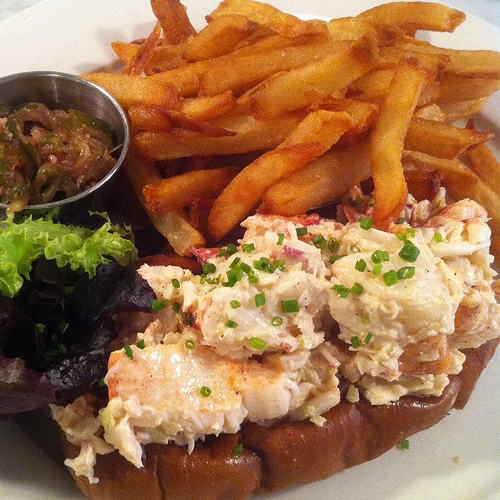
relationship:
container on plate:
[0, 68, 134, 224] [385, 467, 456, 490]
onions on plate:
[47, 218, 498, 477] [7, 0, 498, 495]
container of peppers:
[0, 59, 140, 249] [0, 87, 117, 201]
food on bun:
[7, 187, 494, 500] [122, 417, 381, 500]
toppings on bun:
[216, 259, 374, 315] [122, 417, 381, 500]